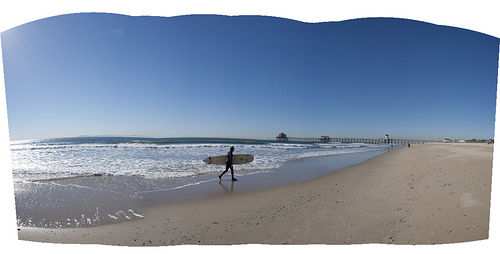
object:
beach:
[18, 141, 493, 246]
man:
[218, 146, 237, 181]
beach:
[205, 141, 493, 244]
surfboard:
[203, 154, 254, 165]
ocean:
[16, 133, 220, 175]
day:
[7, 30, 484, 238]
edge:
[284, 149, 492, 245]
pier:
[275, 132, 416, 144]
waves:
[23, 140, 320, 178]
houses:
[443, 138, 495, 144]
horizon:
[9, 134, 314, 145]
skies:
[3, 13, 495, 133]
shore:
[158, 163, 490, 236]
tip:
[203, 156, 212, 164]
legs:
[230, 165, 237, 181]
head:
[230, 146, 235, 152]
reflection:
[12, 138, 62, 176]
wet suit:
[218, 151, 235, 179]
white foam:
[12, 146, 188, 176]